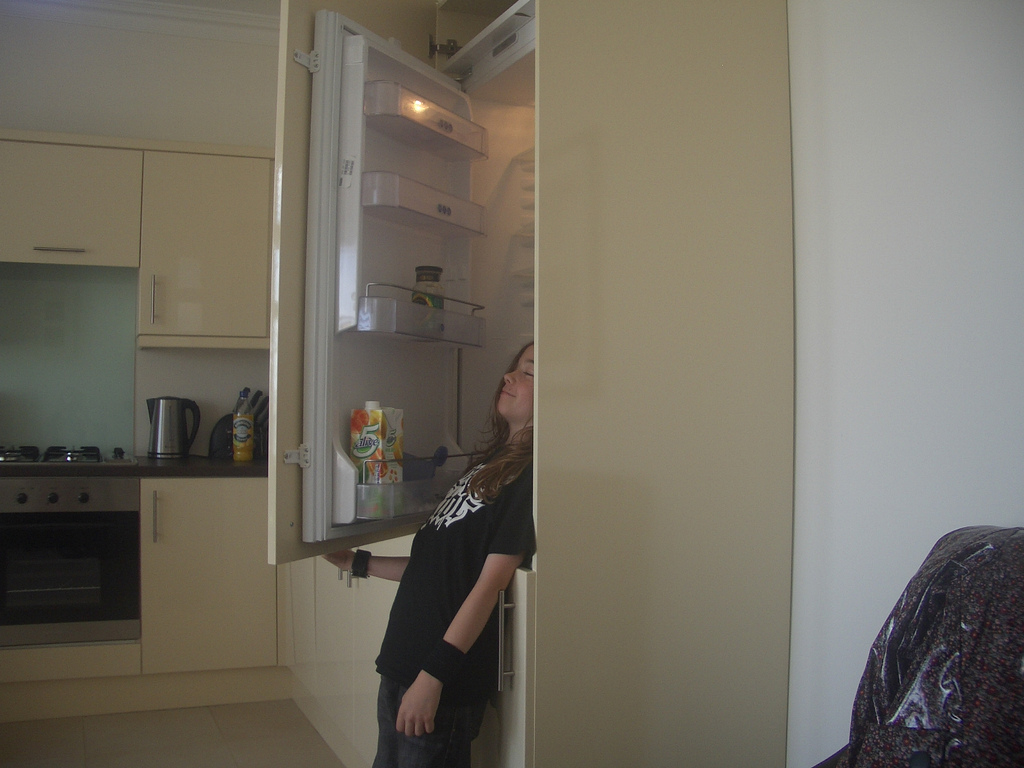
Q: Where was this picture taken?
A: A kitchen.